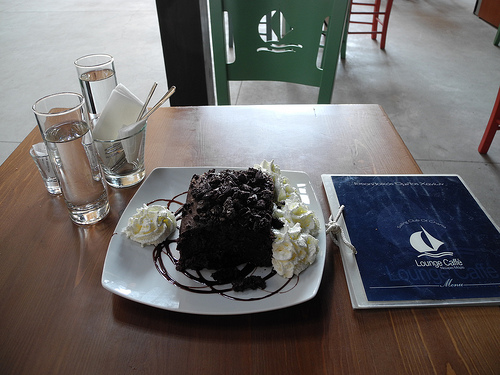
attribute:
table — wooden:
[2, 102, 498, 375]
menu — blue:
[318, 165, 499, 314]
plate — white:
[98, 164, 331, 322]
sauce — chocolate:
[143, 177, 303, 304]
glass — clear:
[28, 88, 116, 230]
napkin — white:
[84, 78, 181, 168]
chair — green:
[206, 0, 356, 105]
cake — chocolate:
[175, 167, 283, 273]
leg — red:
[474, 80, 499, 177]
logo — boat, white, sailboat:
[400, 221, 471, 276]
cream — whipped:
[119, 199, 181, 253]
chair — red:
[347, 3, 397, 52]